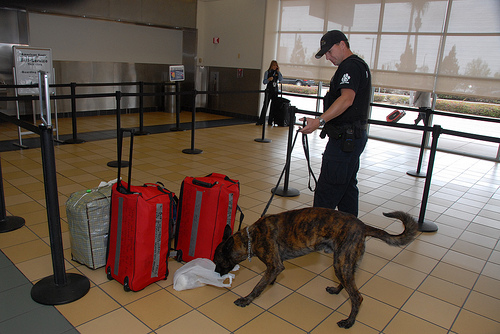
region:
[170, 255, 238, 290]
a white plastic bag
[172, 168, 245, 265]
a red and gray suitcase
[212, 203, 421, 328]
a large dog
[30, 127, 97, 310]
a black pole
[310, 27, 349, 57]
a black baseball cap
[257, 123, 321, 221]
a long black leash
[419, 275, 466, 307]
a piece of floor tile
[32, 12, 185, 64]
a long white wall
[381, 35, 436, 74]
a window of a building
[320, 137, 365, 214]
the leg of a man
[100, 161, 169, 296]
RED PIECE OF LUGGAGE WITH HANDLE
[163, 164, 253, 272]
RED PIECE OF LUGGAGE WITH HANDLE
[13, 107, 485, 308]
TAN COLORED TILES ON FLOOR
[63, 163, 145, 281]
GRAY PIECE OF LUGGAGE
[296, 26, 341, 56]
BLACK BASEBALL CAP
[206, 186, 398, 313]
BROWN AND BLACK POLICE DOG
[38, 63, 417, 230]
BLACK DIVIDER ROPE FOR LINES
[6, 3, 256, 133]
STAINLESS STEEL WALL IN BACKGROUND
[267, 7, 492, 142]
GLASS WINDOWS BY STREET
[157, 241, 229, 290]
WHITE PLASTIC BAG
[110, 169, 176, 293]
red luggage with wheels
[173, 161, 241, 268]
red luggage with wheels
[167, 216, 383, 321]
dog sniffing white plastic bag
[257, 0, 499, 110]
blinds halfway drawn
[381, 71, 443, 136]
person pulling suitcase on wheels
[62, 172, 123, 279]
silver colored bag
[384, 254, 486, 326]
floor made of two toned tiles and dark grout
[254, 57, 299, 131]
woman with dark large suitcase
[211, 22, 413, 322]
man with dog on leash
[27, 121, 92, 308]
black pole with round base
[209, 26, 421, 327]
Cop brings dog to search bags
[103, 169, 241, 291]
the suitcases are red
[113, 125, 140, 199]
case handle is up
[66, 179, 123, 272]
the bag is clear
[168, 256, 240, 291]
dogs nose in plastic bag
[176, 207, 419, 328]
dog is black and brown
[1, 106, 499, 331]
floor is tan and grey tile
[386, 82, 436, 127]
woman is dragging suit case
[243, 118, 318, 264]
cop is holding leash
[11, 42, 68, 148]
white sign with black writing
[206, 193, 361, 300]
dark brown and black dog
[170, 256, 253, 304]
white plastic bag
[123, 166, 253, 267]
identical red and gray bags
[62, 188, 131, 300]
gray metallic duffle bag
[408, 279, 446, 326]
tan colored tile floor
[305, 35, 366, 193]
man in black outfit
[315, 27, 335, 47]
black cap on man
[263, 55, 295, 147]
woman in black and blue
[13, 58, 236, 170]
rope to guide passengers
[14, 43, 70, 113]
a sign for departures